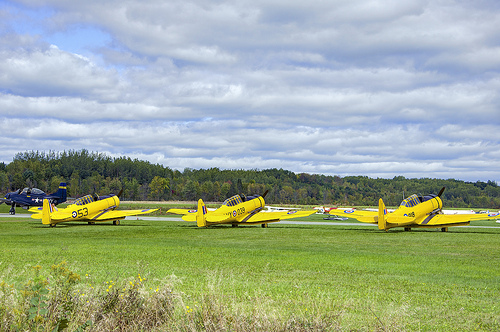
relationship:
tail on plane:
[185, 193, 236, 258] [169, 180, 332, 235]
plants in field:
[18, 268, 183, 329] [50, 216, 371, 327]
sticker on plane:
[308, 204, 357, 206] [316, 185, 490, 242]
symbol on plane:
[177, 190, 217, 211] [119, 182, 322, 231]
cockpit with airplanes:
[221, 175, 270, 204] [173, 180, 355, 256]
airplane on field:
[7, 184, 68, 213] [0, 200, 500, 332]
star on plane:
[31, 197, 47, 205] [6, 178, 75, 213]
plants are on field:
[0, 268, 182, 332] [0, 207, 487, 329]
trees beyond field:
[6, 152, 499, 205] [4, 180, 494, 327]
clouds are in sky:
[0, 0, 500, 147] [7, 11, 491, 166]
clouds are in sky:
[374, 18, 474, 64] [7, 11, 491, 166]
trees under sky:
[6, 144, 496, 206] [7, 8, 489, 146]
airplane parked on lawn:
[0, 182, 67, 215] [12, 219, 485, 290]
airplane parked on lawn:
[26, 193, 157, 228] [12, 219, 485, 290]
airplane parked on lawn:
[166, 190, 317, 228] [12, 219, 485, 290]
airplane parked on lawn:
[312, 186, 500, 232] [12, 219, 485, 290]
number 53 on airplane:
[73, 201, 94, 223] [26, 193, 157, 228]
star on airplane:
[34, 197, 40, 203] [4, 178, 73, 215]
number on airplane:
[225, 203, 249, 219] [166, 183, 317, 231]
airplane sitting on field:
[26, 193, 157, 228] [4, 180, 494, 327]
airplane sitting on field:
[166, 190, 317, 228] [4, 180, 494, 327]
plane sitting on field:
[318, 180, 494, 235] [4, 180, 494, 327]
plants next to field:
[0, 268, 182, 332] [1, 218, 498, 321]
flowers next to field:
[23, 252, 78, 297] [5, 210, 495, 298]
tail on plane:
[367, 198, 402, 232] [318, 180, 494, 235]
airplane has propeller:
[166, 190, 317, 228] [254, 185, 277, 203]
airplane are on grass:
[0, 182, 67, 215] [72, 229, 350, 251]